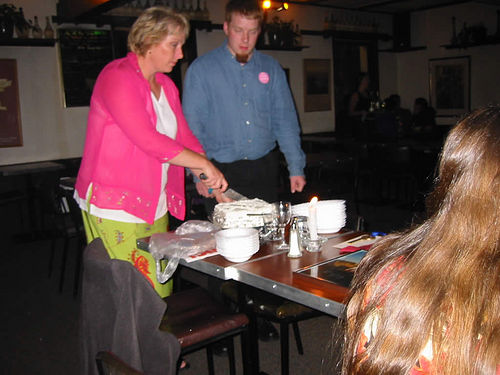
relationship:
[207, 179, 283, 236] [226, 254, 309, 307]
cake on table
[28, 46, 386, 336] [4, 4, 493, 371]
celebration in house